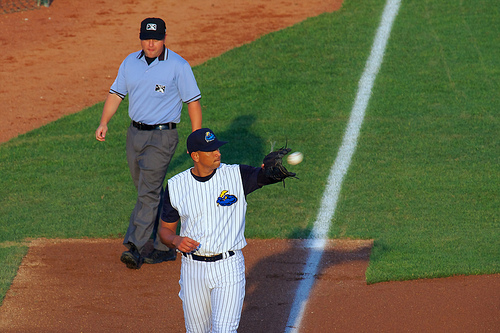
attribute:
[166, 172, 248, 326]
uniform — professional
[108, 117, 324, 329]
player — practicing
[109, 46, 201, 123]
polo — blue 